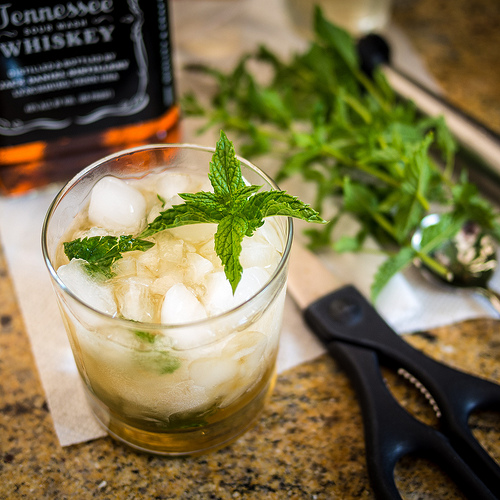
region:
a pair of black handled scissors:
[292, 235, 497, 499]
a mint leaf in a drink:
[141, 132, 328, 286]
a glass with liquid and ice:
[28, 130, 308, 462]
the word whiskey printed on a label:
[2, 22, 121, 58]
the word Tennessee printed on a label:
[1, 0, 112, 27]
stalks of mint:
[297, 0, 499, 287]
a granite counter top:
[0, 443, 315, 498]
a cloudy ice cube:
[88, 173, 148, 235]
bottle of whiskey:
[0, 1, 189, 195]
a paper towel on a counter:
[0, 131, 499, 449]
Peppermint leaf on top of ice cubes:
[148, 139, 326, 290]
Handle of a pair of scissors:
[302, 292, 499, 498]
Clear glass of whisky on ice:
[37, 140, 302, 457]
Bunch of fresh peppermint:
[300, 61, 491, 274]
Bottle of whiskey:
[3, 4, 183, 145]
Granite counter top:
[16, 449, 333, 494]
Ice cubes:
[138, 253, 218, 310]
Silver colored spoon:
[406, 213, 498, 312]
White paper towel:
[3, 110, 466, 362]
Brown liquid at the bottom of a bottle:
[0, 105, 184, 162]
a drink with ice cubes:
[53, 122, 373, 467]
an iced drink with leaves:
[68, 126, 388, 408]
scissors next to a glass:
[230, 172, 498, 461]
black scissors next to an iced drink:
[85, 110, 459, 470]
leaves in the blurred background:
[222, 39, 424, 313]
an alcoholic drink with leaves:
[23, 9, 217, 334]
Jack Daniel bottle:
[14, 1, 257, 227]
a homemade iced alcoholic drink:
[53, 81, 452, 466]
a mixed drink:
[10, 37, 415, 480]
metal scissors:
[154, 105, 492, 437]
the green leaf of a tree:
[206, 125, 243, 209]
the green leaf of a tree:
[245, 186, 317, 228]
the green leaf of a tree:
[209, 208, 249, 282]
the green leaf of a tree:
[139, 204, 217, 241]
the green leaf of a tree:
[238, 181, 261, 204]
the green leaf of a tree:
[178, 186, 220, 215]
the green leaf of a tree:
[378, 237, 408, 308]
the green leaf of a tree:
[419, 205, 465, 252]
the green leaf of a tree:
[396, 147, 431, 235]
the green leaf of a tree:
[269, 152, 331, 184]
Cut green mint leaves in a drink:
[195, 130, 291, 266]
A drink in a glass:
[31, 170, 291, 451]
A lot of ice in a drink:
[46, 147, 283, 417]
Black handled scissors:
[285, 240, 480, 481]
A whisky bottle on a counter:
[10, 5, 200, 150]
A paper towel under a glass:
[32, 297, 167, 462]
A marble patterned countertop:
[291, 392, 356, 467]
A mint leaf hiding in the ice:
[112, 300, 169, 360]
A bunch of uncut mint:
[217, 26, 473, 261]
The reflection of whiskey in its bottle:
[5, 99, 206, 191]